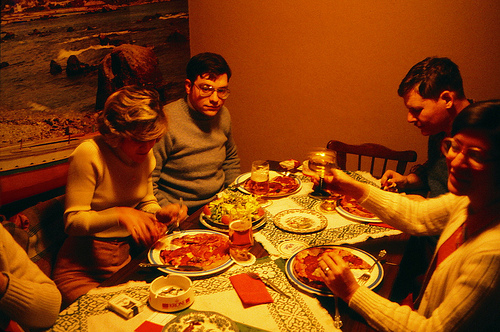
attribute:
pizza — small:
[162, 235, 230, 274]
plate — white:
[147, 228, 240, 277]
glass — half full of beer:
[226, 206, 254, 257]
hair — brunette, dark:
[187, 51, 229, 81]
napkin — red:
[229, 271, 267, 306]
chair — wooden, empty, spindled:
[323, 136, 414, 179]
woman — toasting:
[317, 102, 495, 328]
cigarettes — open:
[107, 292, 141, 318]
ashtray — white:
[146, 277, 195, 308]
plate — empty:
[272, 208, 329, 233]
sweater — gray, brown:
[155, 98, 240, 203]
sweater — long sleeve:
[63, 137, 162, 241]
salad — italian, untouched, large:
[207, 190, 265, 224]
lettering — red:
[160, 297, 195, 310]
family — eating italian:
[2, 46, 499, 330]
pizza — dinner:
[296, 247, 357, 287]